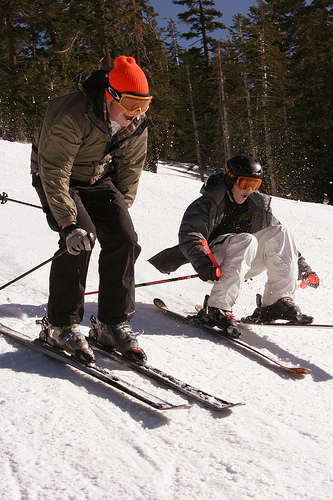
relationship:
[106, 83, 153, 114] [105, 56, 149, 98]
goggle around beanie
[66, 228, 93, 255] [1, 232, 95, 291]
hand holding pole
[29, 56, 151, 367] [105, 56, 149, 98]
man wearing beanie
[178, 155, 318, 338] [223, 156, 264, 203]
man has helmet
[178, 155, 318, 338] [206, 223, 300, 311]
man wearing pants